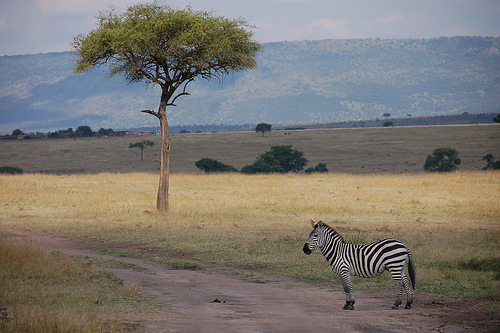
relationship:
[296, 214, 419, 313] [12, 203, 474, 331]
zebra on road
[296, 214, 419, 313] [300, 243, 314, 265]
zebra has snout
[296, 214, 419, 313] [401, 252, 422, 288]
zebra has tail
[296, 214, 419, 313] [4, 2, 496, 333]
zebra on plains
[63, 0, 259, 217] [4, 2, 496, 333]
tree on plains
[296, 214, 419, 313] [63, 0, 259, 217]
zebra near tree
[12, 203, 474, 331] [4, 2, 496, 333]
road on plains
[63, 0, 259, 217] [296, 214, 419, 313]
tree next to zebra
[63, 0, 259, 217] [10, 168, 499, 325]
tree in field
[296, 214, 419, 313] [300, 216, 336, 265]
zebra has head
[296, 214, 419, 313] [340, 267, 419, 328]
zebra has legs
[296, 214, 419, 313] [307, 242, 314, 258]
zebra has mouth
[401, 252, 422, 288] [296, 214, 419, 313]
tail of zebra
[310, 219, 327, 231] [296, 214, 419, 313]
ears of zebra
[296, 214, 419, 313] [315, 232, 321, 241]
zebra has eye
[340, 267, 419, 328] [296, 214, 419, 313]
legs of zebra